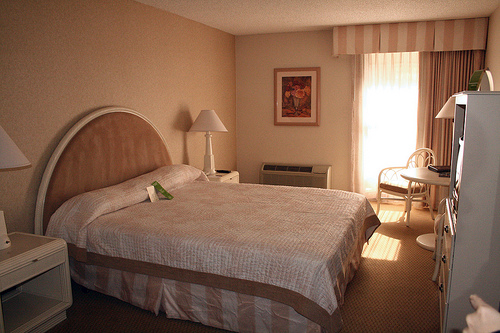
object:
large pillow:
[69, 163, 202, 216]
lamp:
[188, 109, 228, 177]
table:
[0, 227, 37, 249]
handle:
[444, 225, 449, 233]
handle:
[442, 255, 446, 264]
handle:
[439, 283, 444, 292]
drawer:
[442, 197, 456, 269]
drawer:
[438, 233, 448, 329]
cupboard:
[437, 90, 500, 333]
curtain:
[331, 16, 486, 210]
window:
[356, 51, 419, 194]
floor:
[346, 195, 434, 331]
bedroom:
[0, 1, 500, 333]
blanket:
[43, 163, 381, 333]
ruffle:
[281, 76, 311, 117]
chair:
[376, 148, 438, 227]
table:
[405, 169, 450, 180]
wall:
[233, 30, 350, 186]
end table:
[203, 169, 240, 183]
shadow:
[172, 106, 194, 166]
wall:
[0, 0, 234, 232]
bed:
[34, 107, 382, 333]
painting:
[273, 67, 321, 126]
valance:
[332, 17, 488, 58]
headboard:
[34, 107, 172, 236]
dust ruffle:
[44, 163, 381, 332]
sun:
[364, 87, 414, 149]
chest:
[0, 231, 73, 333]